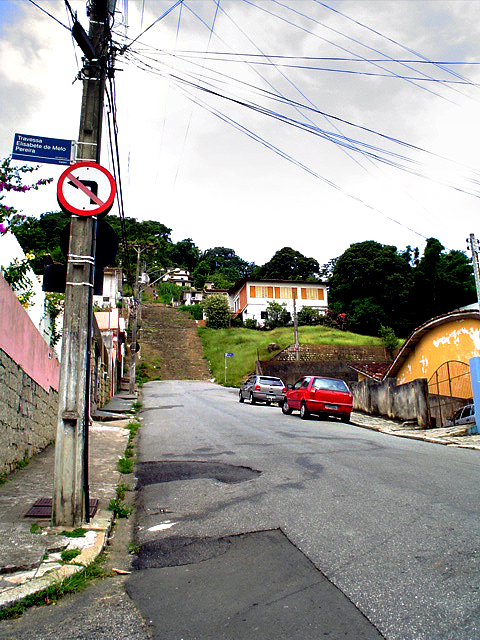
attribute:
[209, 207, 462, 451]
house — white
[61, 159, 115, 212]
sign — white, red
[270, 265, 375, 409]
car — red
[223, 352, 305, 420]
car — grey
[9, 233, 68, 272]
flower — yellow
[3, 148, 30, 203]
flower — purple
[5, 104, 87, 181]
sign — blue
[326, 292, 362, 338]
flower — red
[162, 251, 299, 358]
bush — green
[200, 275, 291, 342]
bush — green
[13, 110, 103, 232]
sign — blue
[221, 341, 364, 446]
car — red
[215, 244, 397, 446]
house — white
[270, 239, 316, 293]
tree — green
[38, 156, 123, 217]
sign — white, red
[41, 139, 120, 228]
sign — red, white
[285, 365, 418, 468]
car — red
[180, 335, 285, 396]
car — grey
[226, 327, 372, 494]
cars — parked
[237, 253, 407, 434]
house — white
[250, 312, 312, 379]
grass — green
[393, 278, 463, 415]
building — orange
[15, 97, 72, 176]
sign — blue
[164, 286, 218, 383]
dirt — brown